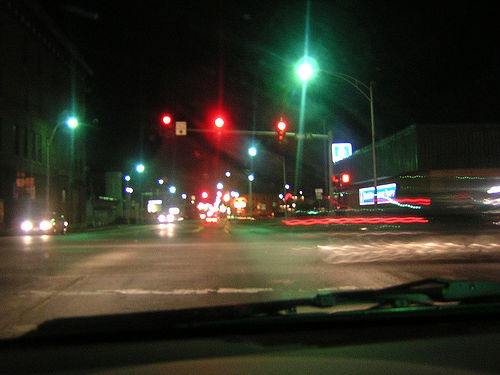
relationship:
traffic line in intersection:
[25, 285, 378, 297] [1, 234, 427, 339]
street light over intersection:
[292, 55, 322, 86] [1, 234, 427, 339]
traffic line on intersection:
[25, 285, 378, 297] [1, 234, 427, 339]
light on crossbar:
[272, 117, 291, 140] [158, 125, 336, 142]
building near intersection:
[332, 121, 500, 213] [1, 234, 427, 339]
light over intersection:
[272, 117, 291, 140] [1, 234, 427, 339]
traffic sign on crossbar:
[173, 120, 190, 138] [158, 125, 336, 142]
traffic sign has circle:
[173, 120, 190, 138] [179, 130, 185, 135]